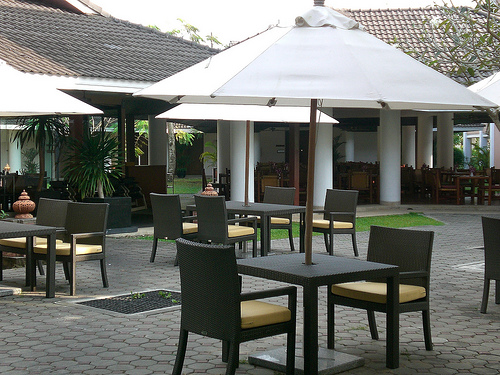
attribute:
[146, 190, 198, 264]
chair — black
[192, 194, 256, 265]
chair — black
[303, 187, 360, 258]
chair — black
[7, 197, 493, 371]
patio — brick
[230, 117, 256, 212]
pillar — white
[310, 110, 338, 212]
pillar — white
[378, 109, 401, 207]
pillar — white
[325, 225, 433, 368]
chair — black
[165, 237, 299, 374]
chair — black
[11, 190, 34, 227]
urn — Decorative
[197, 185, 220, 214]
urn — Decorative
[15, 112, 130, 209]
trees — palm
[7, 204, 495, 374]
ground — grey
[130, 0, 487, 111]
umbrella — round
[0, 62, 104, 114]
umbrella — round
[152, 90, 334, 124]
umbrella — round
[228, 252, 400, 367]
table — rectangular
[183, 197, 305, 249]
table — square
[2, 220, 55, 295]
table — square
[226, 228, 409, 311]
table — empty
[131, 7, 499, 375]
umbrella — white, large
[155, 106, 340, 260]
umbrella — white, large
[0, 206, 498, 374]
floor — grey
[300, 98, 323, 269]
pole — brown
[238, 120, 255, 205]
pole — brown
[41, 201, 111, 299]
chair — black, tan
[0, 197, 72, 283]
chair — black, tan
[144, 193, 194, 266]
chair — black, tan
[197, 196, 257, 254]
chair — black, tan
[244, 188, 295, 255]
chair — black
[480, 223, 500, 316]
chair — black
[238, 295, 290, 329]
cushion — tan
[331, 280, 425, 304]
cushion — tan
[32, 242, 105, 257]
cushion — tan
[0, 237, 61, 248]
cushion — tan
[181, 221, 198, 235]
cushion — tan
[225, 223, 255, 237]
cushion — tan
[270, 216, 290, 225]
cushion — tan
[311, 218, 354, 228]
cushion — tan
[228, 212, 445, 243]
grass — green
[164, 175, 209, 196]
grass — green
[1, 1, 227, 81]
roof — brown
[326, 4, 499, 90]
roof — brown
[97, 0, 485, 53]
sky — white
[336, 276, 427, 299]
cushion — yellow